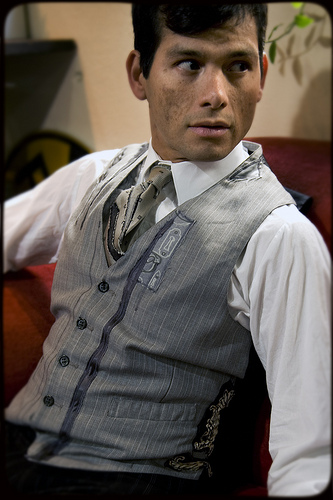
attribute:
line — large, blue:
[38, 215, 175, 461]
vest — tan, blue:
[4, 143, 297, 482]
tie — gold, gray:
[102, 161, 173, 264]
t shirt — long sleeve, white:
[3, 138, 330, 496]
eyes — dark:
[227, 59, 252, 75]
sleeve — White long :
[245, 201, 312, 272]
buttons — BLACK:
[59, 271, 126, 343]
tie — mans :
[89, 135, 187, 251]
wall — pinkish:
[1, 4, 332, 157]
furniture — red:
[3, 137, 327, 491]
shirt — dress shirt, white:
[0, 137, 332, 499]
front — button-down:
[13, 126, 239, 450]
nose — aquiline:
[199, 67, 227, 110]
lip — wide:
[192, 125, 232, 140]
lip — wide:
[194, 118, 234, 128]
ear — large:
[126, 53, 149, 97]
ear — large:
[260, 52, 271, 100]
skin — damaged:
[126, 20, 269, 159]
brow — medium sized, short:
[167, 43, 200, 57]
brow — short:
[228, 46, 250, 56]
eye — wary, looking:
[176, 56, 199, 74]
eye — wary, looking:
[228, 60, 251, 77]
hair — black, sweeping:
[130, 5, 268, 56]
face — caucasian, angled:
[151, 16, 261, 159]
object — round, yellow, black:
[2, 127, 89, 196]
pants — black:
[1, 418, 210, 499]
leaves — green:
[293, 11, 315, 27]